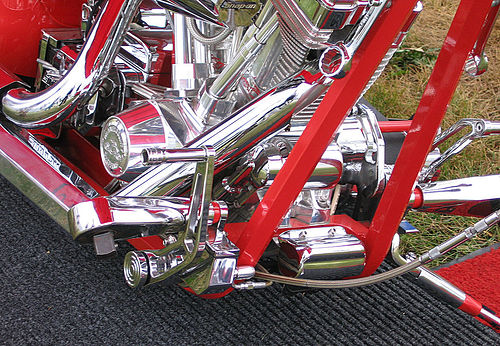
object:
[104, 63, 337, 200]
tube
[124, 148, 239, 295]
pedal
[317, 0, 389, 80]
wrench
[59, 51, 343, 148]
reflection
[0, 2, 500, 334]
chrome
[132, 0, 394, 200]
suspension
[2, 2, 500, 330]
motorcycle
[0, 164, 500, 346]
carpet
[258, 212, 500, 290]
cable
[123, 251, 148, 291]
metal screw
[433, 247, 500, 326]
red mat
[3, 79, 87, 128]
reflection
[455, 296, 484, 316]
tape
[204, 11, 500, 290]
bar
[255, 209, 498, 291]
brake line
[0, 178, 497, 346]
mat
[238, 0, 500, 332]
frame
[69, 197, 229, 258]
ratchet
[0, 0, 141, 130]
exhaust tube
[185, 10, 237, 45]
metal hose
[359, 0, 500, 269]
grass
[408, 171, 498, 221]
foot rest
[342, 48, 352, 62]
silver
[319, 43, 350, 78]
metal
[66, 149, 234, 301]
foot rest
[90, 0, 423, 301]
motorcycle engine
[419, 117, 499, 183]
gear selector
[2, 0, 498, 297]
paint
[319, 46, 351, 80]
wrench head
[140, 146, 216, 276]
break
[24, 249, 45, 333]
grooves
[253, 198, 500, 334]
bottom